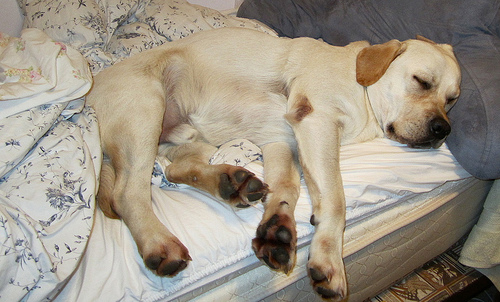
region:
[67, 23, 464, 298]
a light colored dog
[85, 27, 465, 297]
a light colored dog sleeping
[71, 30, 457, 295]
a light colored dog lying down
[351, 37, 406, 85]
the dog's right ear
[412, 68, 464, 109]
the dog's two eyes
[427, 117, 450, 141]
the dog's nose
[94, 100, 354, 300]
the dog's legs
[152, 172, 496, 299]
the uncovered mattress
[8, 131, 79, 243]
the light colored comforter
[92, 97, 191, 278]
the dog's back right leg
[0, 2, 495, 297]
a white and brown dog on the bed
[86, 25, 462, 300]
a dog sleeping in the bed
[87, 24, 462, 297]
a white and tan dog with brown ears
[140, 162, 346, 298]
a dog sleeping on top of a sheet on a mattress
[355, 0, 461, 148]
the dog's head against a blue pillow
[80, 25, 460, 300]
a dog lying down in the bed sleeping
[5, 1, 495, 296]
a dog asleep in the bed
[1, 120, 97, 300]
a comforter on the dog's bed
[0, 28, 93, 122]
a blanket on top of a comforter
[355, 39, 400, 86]
the right brown ear of the dog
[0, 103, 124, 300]
A white sheet with a blue pattern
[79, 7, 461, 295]
A sleepy dog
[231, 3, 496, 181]
A gray comforter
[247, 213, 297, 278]
Large paw of a dog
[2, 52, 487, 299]
The mattress of the bed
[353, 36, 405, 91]
A golden brown dog ear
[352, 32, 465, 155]
A dog's head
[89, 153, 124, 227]
The dog's tail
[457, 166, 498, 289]
A light blue towel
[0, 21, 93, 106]
A white sheet with a pink and green design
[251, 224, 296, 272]
the dogs paw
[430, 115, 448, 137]
the dogs nose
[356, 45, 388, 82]
the dogs ear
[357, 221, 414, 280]
the mattress is white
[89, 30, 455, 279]
dog is laying on the bed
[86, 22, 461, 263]
the dog is white and brown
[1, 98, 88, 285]
the comforter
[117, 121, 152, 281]
the dogs back leg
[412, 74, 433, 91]
the dogs eye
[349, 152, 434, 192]
the sheet on the bed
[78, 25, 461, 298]
sleeping puppy on bed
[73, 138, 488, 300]
mattress on which puppy is sleeping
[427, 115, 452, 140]
black nose of puppy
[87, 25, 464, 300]
light tan puppy sleeping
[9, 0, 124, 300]
blue and white bed linens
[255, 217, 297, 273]
bottom of dog's front paw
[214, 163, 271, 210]
bottom of dog's back paw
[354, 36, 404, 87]
tan dog's ear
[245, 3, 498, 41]
blue gray comforter on bed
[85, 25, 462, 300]
dog sleeping with head on comforter